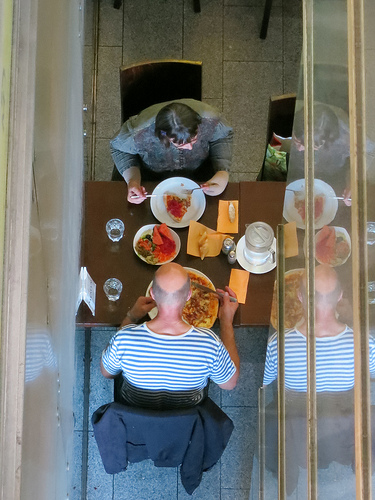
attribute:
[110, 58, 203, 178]
chair — wooden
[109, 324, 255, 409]
shirt — striped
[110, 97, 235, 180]
shirt — gray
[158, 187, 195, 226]
pizza slice — sliced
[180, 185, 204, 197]
silverfork — silver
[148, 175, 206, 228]
plate — white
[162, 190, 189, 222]
pizza — sliced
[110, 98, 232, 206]
woman — eating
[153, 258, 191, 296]
bald head — bright 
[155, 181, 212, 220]
plate — white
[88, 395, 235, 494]
jacket — black, hanging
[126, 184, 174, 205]
utensil — silver, knife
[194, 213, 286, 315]
napkins — orange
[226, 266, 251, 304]
napkin — orange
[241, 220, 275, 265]
pitcher — clear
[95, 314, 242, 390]
shirt — blue, white, striped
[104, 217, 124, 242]
glass — clear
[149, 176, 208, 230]
white plate — large 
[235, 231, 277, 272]
white plate — large 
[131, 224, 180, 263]
white plate — large 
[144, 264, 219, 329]
white plate — large 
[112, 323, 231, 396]
striped — blue and white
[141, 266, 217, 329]
plate — white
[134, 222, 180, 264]
plate — white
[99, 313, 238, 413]
shirt — striped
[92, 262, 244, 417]
man — partially bald